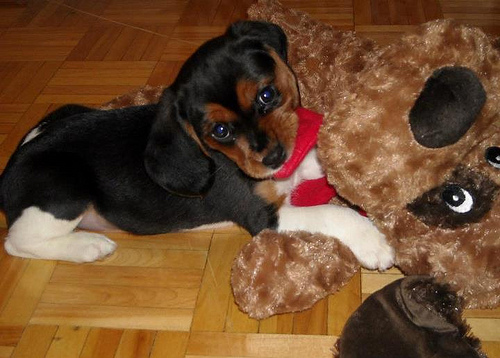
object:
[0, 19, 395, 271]
puppy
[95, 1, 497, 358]
stuffed dog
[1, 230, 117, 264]
foot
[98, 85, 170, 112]
foot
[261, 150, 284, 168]
nose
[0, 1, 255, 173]
floor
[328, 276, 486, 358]
ear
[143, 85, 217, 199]
ear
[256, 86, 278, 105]
eye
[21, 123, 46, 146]
spot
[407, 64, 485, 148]
nose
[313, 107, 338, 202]
bow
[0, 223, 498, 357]
floor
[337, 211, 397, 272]
paw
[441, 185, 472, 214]
eye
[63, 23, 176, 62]
square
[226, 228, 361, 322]
arm